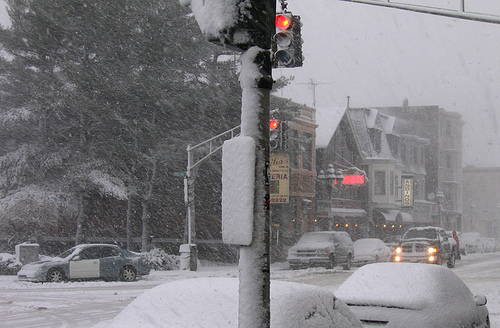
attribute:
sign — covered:
[216, 131, 262, 250]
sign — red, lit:
[341, 173, 366, 184]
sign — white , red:
[265, 150, 291, 211]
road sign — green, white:
[173, 170, 188, 176]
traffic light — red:
[273, 7, 308, 69]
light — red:
[275, 11, 290, 32]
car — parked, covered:
[112, 272, 368, 327]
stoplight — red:
[269, 3, 322, 85]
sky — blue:
[358, 36, 431, 100]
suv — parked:
[280, 223, 357, 278]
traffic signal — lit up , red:
[265, 2, 308, 74]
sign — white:
[266, 165, 293, 208]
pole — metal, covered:
[200, 6, 293, 324]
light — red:
[269, 117, 277, 129]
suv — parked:
[287, 230, 355, 274]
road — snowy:
[0, 250, 499, 326]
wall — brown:
[284, 165, 325, 204]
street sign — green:
[160, 157, 211, 199]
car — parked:
[336, 261, 484, 323]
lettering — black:
[271, 170, 293, 204]